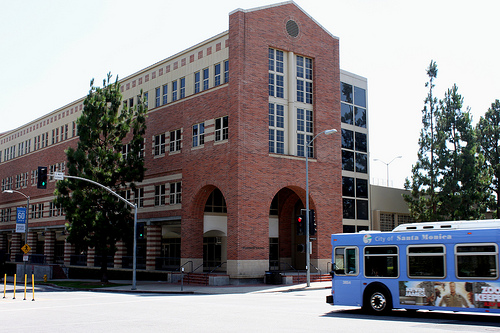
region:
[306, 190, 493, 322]
A blue bus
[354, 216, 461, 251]
Bus owned by the City of Santa Monica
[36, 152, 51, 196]
The stoplight is green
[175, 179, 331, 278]
Two archways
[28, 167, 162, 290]
Stoplight attached to a metal pole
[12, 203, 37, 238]
The sign says the number 60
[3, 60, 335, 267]
The building is made of brick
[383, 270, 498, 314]
Advertisement for the movie Zookeeper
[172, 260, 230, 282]
A short flight of stairs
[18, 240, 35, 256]
Pedestrian crossing sign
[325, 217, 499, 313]
part of a blue bus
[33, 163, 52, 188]
a black street light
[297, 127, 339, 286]
a tall gray street light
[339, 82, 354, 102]
a window of a building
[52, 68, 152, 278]
a tall green tree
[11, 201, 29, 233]
a blue and white flag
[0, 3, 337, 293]
a large brick building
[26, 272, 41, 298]
a yellow pole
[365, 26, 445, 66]
part of a white sky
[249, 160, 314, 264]
arched opening to brick building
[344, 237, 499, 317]
blue bus with dark windows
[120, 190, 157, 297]
pole holding traffic signal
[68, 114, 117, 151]
dark green leaves on tree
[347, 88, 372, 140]
dark windows in brick building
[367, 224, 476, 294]
bus is blue with white letters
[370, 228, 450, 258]
city bus for city of Santa monica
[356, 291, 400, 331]
chrome wheel on city bus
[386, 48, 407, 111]
sky is bright and white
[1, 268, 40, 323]
4 yellow poles in street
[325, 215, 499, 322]
The bus is blue.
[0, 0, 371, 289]
The building is made of bricks.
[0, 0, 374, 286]
The building is large.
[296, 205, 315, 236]
The light is red.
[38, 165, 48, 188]
The light is green.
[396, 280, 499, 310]
The ad is for Zoo Keeper.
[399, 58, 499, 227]
The trees are tall.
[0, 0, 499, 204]
The sky is cloudy.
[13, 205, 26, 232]
The sign says 60.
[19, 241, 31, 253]
The sign is yellow.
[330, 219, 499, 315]
Blue bus on a street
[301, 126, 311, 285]
Tall gray metal pole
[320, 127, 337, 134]
Street light on a pole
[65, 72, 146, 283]
Tall pine tree near a building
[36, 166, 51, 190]
Black metal traffic light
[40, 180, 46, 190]
Green light in traffic light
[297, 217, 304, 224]
Red light in traffic light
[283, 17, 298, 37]
Round window on top of building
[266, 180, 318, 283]
Arched entryway of building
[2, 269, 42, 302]
Yellow posts near the street